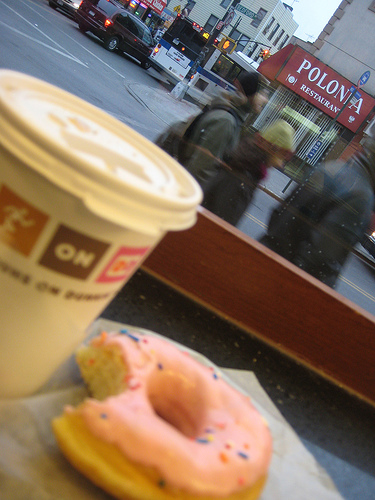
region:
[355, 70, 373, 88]
A round blue and white bus stop sign.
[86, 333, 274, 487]
Pink frosting.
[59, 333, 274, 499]
A donut with a bite taken out of it.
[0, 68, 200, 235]
A white lid.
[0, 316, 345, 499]
A piece of wax paper.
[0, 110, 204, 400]
A white Dunkin Donuts cup.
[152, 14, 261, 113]
A blue and white bus.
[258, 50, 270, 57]
A traffic light.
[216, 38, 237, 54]
A yellow crosswalk sign.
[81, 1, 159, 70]
A dark colored minivan.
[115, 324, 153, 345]
blue sprinkle on donut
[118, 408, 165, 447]
pink frosting on the donut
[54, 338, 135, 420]
half eaten donut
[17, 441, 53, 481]
white paper under donut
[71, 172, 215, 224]
white lid on coffee cut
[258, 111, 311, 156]
white cap on woman's head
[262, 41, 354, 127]
red sign on top of building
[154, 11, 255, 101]
passenger bus on the street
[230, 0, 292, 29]
green and white street sign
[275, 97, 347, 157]
blinds in front of window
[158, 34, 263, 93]
a blue and white bus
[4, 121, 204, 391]
a cup of coffee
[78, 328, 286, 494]
a dough nut with icing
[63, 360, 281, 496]
a dough nut with pink icing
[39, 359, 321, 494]
a dough nut on a paper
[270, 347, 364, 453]
a black table top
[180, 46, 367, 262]
people walking past a window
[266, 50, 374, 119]
a sign on a store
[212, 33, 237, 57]
a no walk sign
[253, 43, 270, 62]
a street light on a pole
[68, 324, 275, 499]
the donut on the napkin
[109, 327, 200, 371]
sprinkles on the donut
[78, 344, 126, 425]
the bite in the donut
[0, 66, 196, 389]
the coffee beside the donut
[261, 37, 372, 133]
the awning of the restaurant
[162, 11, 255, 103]
the bus on the street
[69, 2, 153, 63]
the minivan on the street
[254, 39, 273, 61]
the traffic light is hanging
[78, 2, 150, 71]
the minivan is burgundy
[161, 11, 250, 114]
the bus is blue and white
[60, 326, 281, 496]
a donut with a bite taken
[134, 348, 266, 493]
a donut with pink icing and colorful sprinkles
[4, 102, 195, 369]
a Styrofoam cup of coffee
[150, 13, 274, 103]
A bus stopped at the corner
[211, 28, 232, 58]
a traffic signal showing don't walk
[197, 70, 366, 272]
a group of people walking down the street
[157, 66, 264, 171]
person with a backpack wearing a cap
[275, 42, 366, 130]
name of restaurant on red awning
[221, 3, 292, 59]
a building with multiple windows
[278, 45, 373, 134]
a sign for Polonia Restaurant